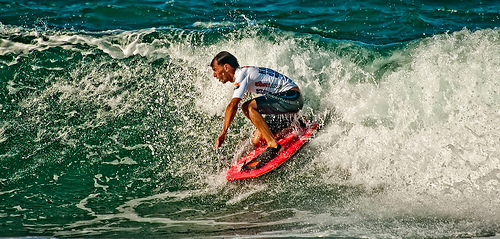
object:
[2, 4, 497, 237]
water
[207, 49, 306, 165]
man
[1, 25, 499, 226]
wave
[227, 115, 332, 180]
surfboard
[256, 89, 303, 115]
shorts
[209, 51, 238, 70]
hair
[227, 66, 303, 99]
top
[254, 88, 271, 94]
writing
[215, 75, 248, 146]
arm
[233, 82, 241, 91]
emblem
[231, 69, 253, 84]
shoulder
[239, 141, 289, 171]
flipper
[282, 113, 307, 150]
flipper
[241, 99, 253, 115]
knee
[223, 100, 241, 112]
elbow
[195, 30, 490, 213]
foam